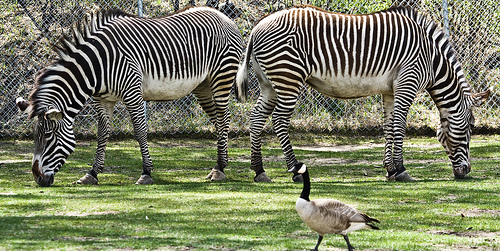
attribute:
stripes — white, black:
[321, 27, 404, 69]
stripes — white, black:
[142, 30, 206, 73]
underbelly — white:
[318, 70, 388, 103]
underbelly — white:
[143, 76, 202, 109]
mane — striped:
[409, 5, 486, 118]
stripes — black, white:
[421, 6, 481, 89]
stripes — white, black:
[61, 26, 100, 58]